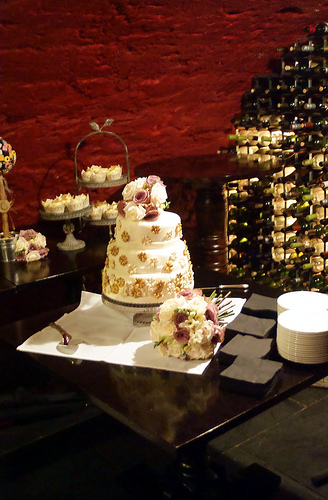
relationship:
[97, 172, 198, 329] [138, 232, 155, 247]
wedding cake has a gold flower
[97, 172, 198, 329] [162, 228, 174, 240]
wedding cake has a gold flower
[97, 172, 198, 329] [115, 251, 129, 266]
wedding cake has a gold flower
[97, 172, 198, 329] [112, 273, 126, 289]
wedding cake has a gold flower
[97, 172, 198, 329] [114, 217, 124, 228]
wedding cake has a gold flower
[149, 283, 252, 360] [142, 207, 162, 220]
bouquet of flower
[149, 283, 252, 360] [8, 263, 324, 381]
bouquet on table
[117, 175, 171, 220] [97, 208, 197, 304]
bouquet on cake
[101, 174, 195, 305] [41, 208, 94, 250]
cake on stand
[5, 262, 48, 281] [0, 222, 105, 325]
reflection on table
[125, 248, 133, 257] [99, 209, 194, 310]
frosting on cake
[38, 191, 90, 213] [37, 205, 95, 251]
cupcakes on stand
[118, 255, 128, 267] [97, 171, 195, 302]
frosting on wedding cake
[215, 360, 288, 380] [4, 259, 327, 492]
napkin on table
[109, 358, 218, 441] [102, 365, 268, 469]
reflection on table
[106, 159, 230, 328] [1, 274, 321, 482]
cake on table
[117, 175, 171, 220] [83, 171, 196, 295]
bouquet on cake